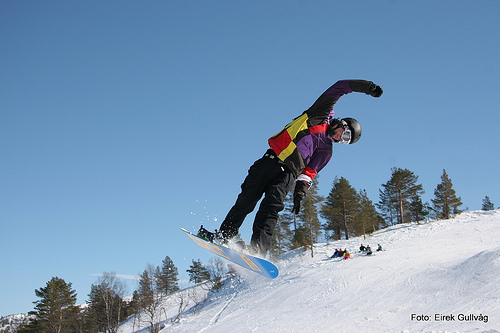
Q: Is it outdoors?
A: Yes, it is outdoors.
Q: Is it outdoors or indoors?
A: It is outdoors.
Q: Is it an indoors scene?
A: No, it is outdoors.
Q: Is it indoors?
A: No, it is outdoors.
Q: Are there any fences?
A: No, there are no fences.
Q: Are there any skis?
A: No, there are no skis.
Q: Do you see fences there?
A: No, there are no fences.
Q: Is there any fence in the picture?
A: No, there are no fences.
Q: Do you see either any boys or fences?
A: No, there are no fences or boys.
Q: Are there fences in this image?
A: No, there are no fences.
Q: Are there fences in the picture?
A: No, there are no fences.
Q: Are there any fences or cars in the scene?
A: No, there are no fences or cars.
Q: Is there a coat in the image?
A: Yes, there is a coat.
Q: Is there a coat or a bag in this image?
A: Yes, there is a coat.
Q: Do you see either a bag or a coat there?
A: Yes, there is a coat.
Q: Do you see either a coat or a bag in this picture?
A: Yes, there is a coat.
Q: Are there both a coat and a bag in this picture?
A: No, there is a coat but no bags.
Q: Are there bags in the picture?
A: No, there are no bags.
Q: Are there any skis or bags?
A: No, there are no bags or skis.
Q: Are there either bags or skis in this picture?
A: No, there are no bags or skis.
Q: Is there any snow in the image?
A: Yes, there is snow.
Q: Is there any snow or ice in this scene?
A: Yes, there is snow.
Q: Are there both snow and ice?
A: No, there is snow but no ice.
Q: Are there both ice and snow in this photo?
A: No, there is snow but no ice.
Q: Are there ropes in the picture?
A: No, there are no ropes.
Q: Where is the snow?
A: The snow is on the mountain.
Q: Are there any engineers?
A: No, there are no engineers.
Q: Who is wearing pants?
A: The athlete is wearing pants.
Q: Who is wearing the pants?
A: The athlete is wearing pants.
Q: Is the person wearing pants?
A: Yes, the athlete is wearing pants.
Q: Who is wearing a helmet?
A: The athlete is wearing a helmet.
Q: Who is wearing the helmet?
A: The athlete is wearing a helmet.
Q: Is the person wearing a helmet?
A: Yes, the athlete is wearing a helmet.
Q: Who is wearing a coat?
A: The athlete is wearing a coat.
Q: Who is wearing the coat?
A: The athlete is wearing a coat.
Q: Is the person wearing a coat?
A: Yes, the athlete is wearing a coat.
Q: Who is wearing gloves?
A: The athlete is wearing gloves.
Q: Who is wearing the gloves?
A: The athlete is wearing gloves.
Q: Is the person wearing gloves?
A: Yes, the athlete is wearing gloves.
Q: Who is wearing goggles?
A: The athlete is wearing goggles.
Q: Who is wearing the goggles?
A: The athlete is wearing goggles.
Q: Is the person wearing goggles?
A: Yes, the athlete is wearing goggles.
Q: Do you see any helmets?
A: Yes, there is a helmet.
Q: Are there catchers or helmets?
A: Yes, there is a helmet.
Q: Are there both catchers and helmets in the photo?
A: No, there is a helmet but no catchers.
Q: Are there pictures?
A: No, there are no pictures.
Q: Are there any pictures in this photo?
A: No, there are no pictures.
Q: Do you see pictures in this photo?
A: No, there are no pictures.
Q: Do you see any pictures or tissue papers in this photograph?
A: No, there are no pictures or tissue papers.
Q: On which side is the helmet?
A: The helmet is on the right of the image.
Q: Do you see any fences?
A: No, there are no fences.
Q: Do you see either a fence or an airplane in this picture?
A: No, there are no fences or airplanes.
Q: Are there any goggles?
A: Yes, there are goggles.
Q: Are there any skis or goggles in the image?
A: Yes, there are goggles.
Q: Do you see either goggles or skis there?
A: Yes, there are goggles.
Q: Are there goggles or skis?
A: Yes, there are goggles.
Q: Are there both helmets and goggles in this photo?
A: Yes, there are both goggles and a helmet.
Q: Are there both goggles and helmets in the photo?
A: Yes, there are both goggles and a helmet.